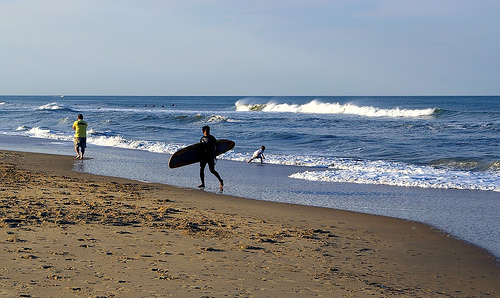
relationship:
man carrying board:
[187, 119, 229, 197] [172, 139, 197, 169]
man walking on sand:
[187, 119, 229, 197] [56, 230, 84, 247]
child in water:
[251, 140, 276, 163] [367, 131, 403, 140]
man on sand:
[187, 119, 229, 197] [56, 230, 84, 247]